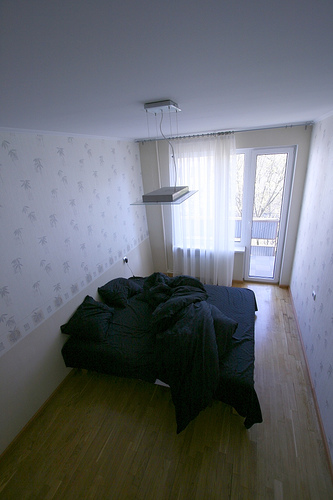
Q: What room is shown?
A: Bedroom.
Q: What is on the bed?
A: Black blankets.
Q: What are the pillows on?
A: A bed.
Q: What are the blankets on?
A: A bed.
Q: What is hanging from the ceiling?
A: A light.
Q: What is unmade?
A: The bed.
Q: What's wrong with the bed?
A: It's unmade.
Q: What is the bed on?
A: The floor.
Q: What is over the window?
A: A curtain.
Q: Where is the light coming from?
A: The window.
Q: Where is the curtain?
A: Over the window.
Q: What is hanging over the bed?
A: Light.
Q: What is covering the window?
A: White sheer curtain.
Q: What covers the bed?
A: Black sheets and comforter.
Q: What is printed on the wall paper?
A: Palm trees or bamboo.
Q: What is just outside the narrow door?
A: Balcony.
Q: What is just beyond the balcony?
A: Bare trees.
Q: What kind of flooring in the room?
A: Wood.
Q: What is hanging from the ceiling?
A: Light fixture.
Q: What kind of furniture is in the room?
A: A bed.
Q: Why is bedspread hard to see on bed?
A: Both black.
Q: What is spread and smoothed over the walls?
A: Wallpaper.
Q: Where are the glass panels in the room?
A: Back wall.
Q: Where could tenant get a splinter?
A: Wood floor.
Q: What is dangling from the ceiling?
A: Light fixture.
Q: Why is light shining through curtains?
A: Sheer curtains.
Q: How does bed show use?
A: Comforter rumpled.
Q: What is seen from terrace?
A: Tree.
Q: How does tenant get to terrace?
A: Glass door.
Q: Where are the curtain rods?
A: Top of wall.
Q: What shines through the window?
A: Light.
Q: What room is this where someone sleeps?
A: Bedroom.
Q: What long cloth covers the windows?
A: Curtain.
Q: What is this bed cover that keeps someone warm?
A: Blanket.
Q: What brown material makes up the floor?
A: Wood.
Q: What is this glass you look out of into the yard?
A: Window.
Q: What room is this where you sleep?
A: Bedroom.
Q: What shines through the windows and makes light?
A: Sun.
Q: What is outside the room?
A: A balcony.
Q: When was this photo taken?
A: During the day.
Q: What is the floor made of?
A: Wood.